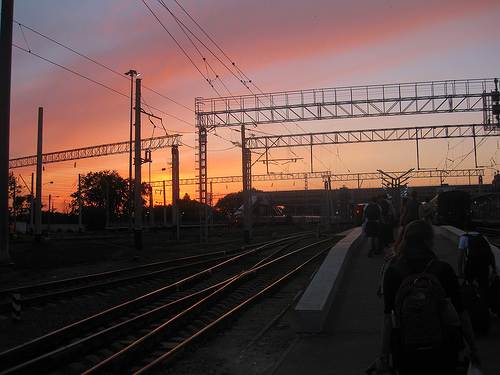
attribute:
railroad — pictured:
[92, 242, 338, 372]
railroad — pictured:
[8, 230, 349, 373]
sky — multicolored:
[4, 5, 498, 202]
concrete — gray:
[272, 226, 342, 332]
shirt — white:
[459, 220, 499, 260]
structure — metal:
[197, 80, 498, 142]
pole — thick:
[28, 100, 48, 204]